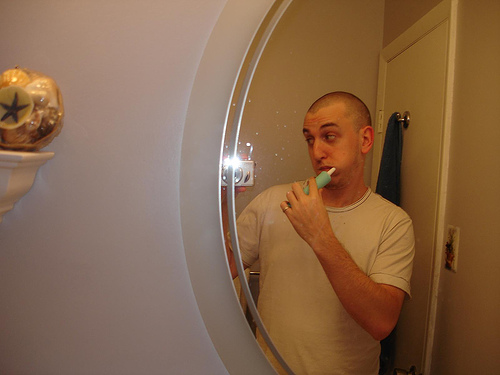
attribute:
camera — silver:
[220, 153, 257, 190]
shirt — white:
[224, 169, 419, 372]